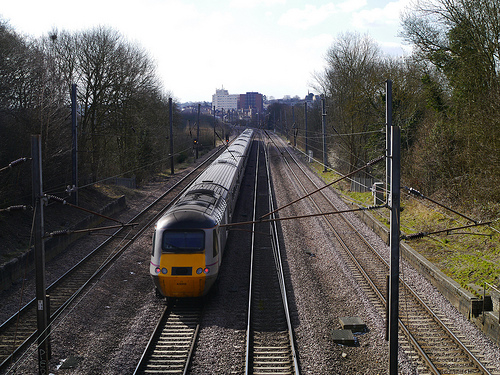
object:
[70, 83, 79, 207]
pole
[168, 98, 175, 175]
pole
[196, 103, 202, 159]
pole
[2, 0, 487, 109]
sky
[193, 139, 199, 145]
light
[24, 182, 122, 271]
retaining wall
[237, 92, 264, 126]
building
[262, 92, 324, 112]
buildings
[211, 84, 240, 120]
building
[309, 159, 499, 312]
grass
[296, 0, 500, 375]
side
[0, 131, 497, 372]
tracks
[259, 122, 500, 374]
rails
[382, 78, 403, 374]
pole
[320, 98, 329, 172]
pole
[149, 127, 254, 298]
train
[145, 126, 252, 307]
white snow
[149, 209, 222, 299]
front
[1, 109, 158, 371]
rails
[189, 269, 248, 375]
gravel